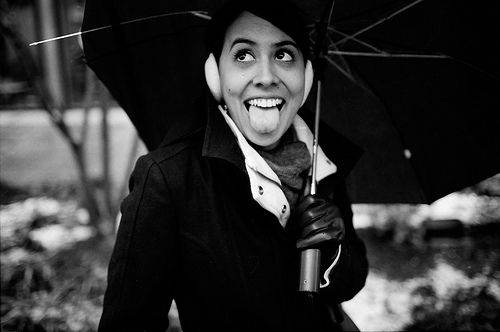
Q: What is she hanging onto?
A: An umbrella.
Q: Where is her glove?
A: On her hand.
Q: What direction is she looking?
A: Up.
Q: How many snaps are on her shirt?
A: Two.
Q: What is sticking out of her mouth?
A: Her tongue.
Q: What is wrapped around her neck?
A: A scarf.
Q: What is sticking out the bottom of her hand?
A: The umbrella handle.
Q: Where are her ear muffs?
A: On her ears.